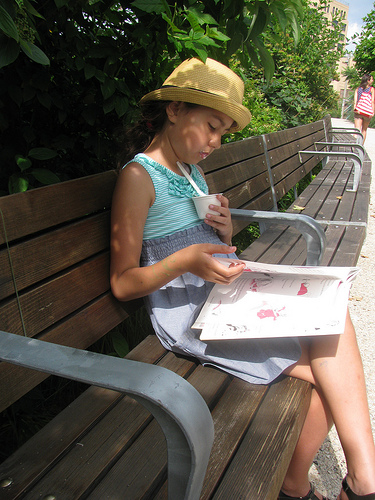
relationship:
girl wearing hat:
[106, 56, 374, 497] [137, 55, 253, 131]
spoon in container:
[174, 163, 208, 197] [189, 195, 223, 220]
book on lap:
[191, 264, 358, 339] [179, 268, 277, 385]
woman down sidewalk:
[353, 76, 374, 135] [307, 117, 374, 499]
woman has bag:
[353, 76, 374, 135] [355, 91, 374, 117]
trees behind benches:
[2, 0, 344, 200] [0, 117, 371, 459]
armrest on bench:
[226, 207, 325, 266] [0, 168, 313, 499]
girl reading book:
[106, 56, 374, 497] [191, 264, 358, 339]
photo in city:
[1, 0, 374, 499] [0, 3, 374, 500]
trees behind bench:
[2, 0, 344, 200] [0, 168, 313, 499]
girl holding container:
[106, 56, 374, 497] [189, 195, 223, 220]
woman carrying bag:
[353, 76, 374, 135] [355, 91, 374, 117]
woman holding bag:
[353, 76, 374, 135] [355, 91, 374, 117]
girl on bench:
[106, 56, 374, 497] [0, 168, 313, 499]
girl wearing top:
[106, 56, 374, 497] [122, 152, 210, 240]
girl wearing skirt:
[106, 56, 374, 497] [139, 222, 303, 385]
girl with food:
[106, 56, 374, 497] [203, 155, 208, 161]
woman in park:
[353, 76, 374, 135] [1, 1, 373, 500]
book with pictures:
[191, 264, 358, 339] [245, 276, 310, 298]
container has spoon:
[189, 195, 223, 220] [174, 163, 208, 197]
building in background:
[307, 0, 344, 92] [0, 0, 374, 143]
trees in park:
[2, 0, 344, 200] [1, 1, 373, 500]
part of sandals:
[342, 482, 356, 496] [279, 478, 373, 500]